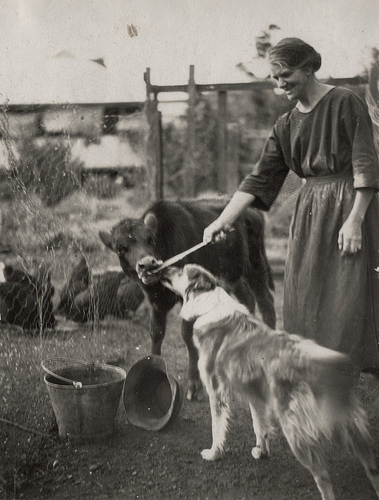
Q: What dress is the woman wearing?
A: A long dress.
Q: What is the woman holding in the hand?
A: A stick.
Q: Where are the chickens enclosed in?
A: In a coop.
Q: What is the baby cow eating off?
A: A stick.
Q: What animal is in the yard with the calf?
A: A dog.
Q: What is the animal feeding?
A: The animals.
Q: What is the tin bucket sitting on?
A: The ground.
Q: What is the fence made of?
A: Chicken wire.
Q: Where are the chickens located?
A: In yard.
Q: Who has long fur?
A: Dog.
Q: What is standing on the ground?
A: Calf.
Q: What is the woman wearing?
A: Long dress.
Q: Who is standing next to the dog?
A: Cow.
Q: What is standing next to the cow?
A: Dog.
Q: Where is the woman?
A: Farm.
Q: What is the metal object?
A: Pail.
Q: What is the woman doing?
A: Feeding animals?.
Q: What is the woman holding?
A: Wooden spoon.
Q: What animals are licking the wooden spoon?
A: Dog and calf.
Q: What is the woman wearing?
A: Long dress.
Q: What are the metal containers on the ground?
A: Buckets.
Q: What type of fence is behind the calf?
A: Wire fence.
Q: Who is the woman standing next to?
A: Animals.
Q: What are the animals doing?
A: Eating.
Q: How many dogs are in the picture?
A: One.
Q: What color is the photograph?
A: Black and white.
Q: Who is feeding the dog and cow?
A: A woman.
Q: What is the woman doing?
A: Feeding the cow and dog.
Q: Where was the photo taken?
A: Farm.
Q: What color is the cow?
A: Black.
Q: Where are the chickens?
A: Behind the cow.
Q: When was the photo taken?
A: Daytime.